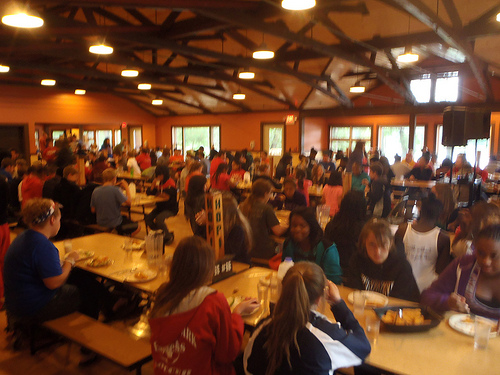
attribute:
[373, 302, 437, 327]
bowl — big, blue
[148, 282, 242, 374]
hoodie — red, white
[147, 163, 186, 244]
boy — yougn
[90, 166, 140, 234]
boy — yougn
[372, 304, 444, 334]
bowl — big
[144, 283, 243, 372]
jacket. — white 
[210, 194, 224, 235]
hop — black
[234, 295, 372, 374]
jacket — blue and white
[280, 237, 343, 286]
jacket — teal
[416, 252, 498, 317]
jacket — purple